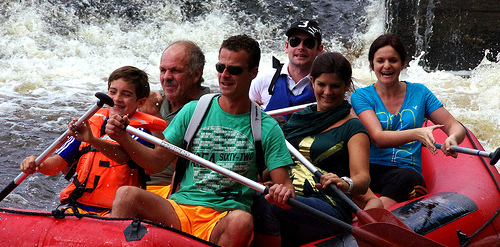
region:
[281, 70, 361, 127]
A woman wearing a green scarf.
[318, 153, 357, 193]
A woman wearing a silver watch.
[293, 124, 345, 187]
Gold leafing painted on a green shirt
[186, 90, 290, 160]
Straps draping over a mans shoulder.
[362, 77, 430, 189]
A woman wearing a blue shirt.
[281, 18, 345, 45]
A man wearing a NASCAR hat.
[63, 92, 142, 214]
A boy wearing an orange life vest.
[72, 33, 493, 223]
A group of people enjoying rafting.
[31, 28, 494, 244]
A group of people sitting in a red raft.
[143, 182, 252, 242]
A man wearing yellow shorts.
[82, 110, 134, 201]
an orange life jacket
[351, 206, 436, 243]
bottoms of two paddles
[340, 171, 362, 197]
a womans watch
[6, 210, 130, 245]
front of the red raft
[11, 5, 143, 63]
the bottom of a waterfall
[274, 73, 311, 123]
a blue life jacket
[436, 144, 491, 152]
the pole on a paddle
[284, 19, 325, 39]
a black and white hat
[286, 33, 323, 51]
a pair of black sunglasses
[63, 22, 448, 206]
a group of people on a raft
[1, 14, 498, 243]
People riding in a raft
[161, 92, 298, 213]
A shirt is green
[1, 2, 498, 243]
Six people are going white water rafting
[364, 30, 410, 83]
Woman has brown hair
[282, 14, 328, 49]
A black and white hat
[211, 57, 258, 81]
The sunglasses are black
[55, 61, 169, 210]
Boy is wearing an orange life vest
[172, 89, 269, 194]
Two straps of a backpack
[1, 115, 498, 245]
The raft is red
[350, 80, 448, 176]
White writing on a blue shirt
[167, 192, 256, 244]
Man wearing shorts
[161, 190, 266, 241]
Man is wearing shorts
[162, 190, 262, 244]
Man wearing yellow shorts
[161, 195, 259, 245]
Man is wearing yellow shorts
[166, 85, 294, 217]
Man wearing a shirt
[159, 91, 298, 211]
Man is wearing a shirt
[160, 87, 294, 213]
Man wearing a green shirt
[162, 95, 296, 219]
Man is wearing a green shirt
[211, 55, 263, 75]
Man wearing sunglasses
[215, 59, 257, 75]
Man is wearing black sunglasses